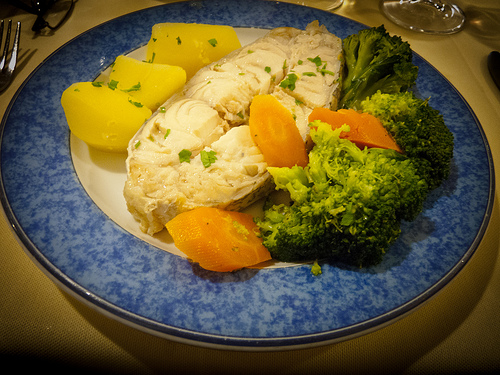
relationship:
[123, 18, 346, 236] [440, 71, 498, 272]
fish on plate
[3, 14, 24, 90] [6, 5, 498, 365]
fork on table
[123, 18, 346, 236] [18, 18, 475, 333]
fish on top of a plate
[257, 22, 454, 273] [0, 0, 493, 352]
broccoli on top of blue plate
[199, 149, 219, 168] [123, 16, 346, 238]
chives on top of fish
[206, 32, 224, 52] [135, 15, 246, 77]
parsley flake on top of potato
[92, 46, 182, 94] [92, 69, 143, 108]
potatoes with herbs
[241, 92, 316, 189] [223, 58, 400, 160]
carrot with broccoli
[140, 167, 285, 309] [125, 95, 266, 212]
carrot next to fish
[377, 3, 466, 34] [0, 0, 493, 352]
clear glass above blue plate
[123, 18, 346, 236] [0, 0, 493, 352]
fish on blue plate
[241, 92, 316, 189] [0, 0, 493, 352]
carrot on blue plate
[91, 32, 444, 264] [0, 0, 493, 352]
food on blue plate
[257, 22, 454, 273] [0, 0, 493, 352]
broccoli on blue plate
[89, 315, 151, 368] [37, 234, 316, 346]
shadow under plate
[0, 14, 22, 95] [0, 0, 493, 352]
fork next to blue plate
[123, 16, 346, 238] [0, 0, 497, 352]
fish on blue plate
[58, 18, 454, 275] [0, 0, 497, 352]
food are on blue plate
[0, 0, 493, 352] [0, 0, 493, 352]
blue plate under blue plate